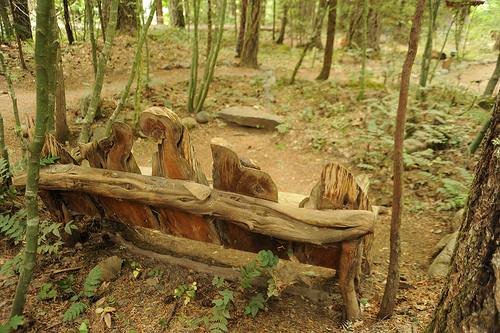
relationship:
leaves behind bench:
[61, 298, 88, 321] [11, 101, 380, 331]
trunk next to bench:
[378, 0, 426, 316] [11, 101, 380, 331]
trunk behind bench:
[6, 0, 57, 325] [11, 101, 380, 331]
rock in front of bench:
[215, 105, 283, 131] [11, 101, 380, 331]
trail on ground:
[0, 43, 495, 146] [1, 26, 500, 331]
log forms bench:
[15, 162, 377, 247] [11, 101, 380, 331]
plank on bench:
[291, 163, 374, 267] [11, 101, 380, 331]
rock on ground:
[215, 105, 283, 131] [1, 26, 500, 331]